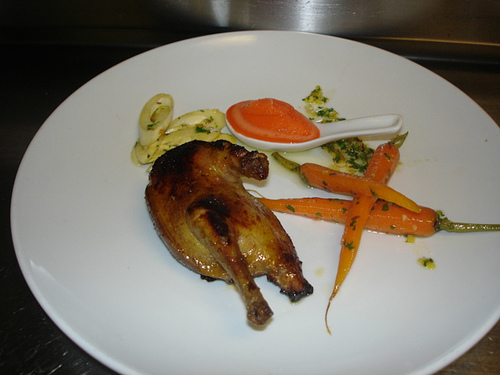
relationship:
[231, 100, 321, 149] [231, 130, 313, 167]
food stuff served in spoon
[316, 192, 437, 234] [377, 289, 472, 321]
carrot on plate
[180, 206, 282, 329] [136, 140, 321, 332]
leg of a chicken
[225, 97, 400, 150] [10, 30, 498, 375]
spoon on dish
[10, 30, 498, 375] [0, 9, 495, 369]
dish on table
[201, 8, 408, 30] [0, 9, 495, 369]
light shining on table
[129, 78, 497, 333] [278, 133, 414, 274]
foods covered with sprinklings